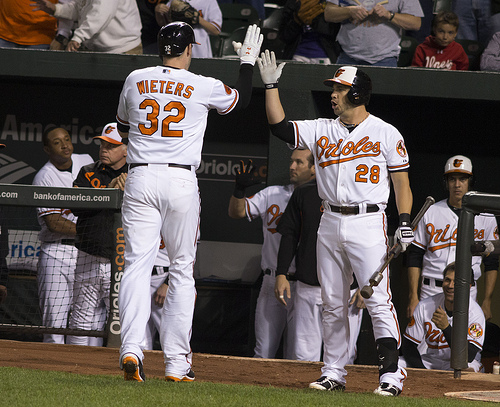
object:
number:
[137, 99, 186, 137]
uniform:
[114, 63, 240, 377]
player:
[405, 154, 499, 321]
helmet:
[444, 155, 475, 191]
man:
[62, 122, 129, 347]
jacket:
[68, 160, 126, 260]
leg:
[347, 215, 409, 398]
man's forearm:
[388, 12, 420, 31]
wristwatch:
[389, 10, 395, 20]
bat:
[361, 196, 436, 298]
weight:
[360, 271, 384, 300]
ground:
[0, 338, 500, 407]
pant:
[316, 201, 408, 393]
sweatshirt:
[414, 36, 469, 71]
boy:
[413, 12, 469, 71]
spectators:
[0, 0, 63, 51]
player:
[255, 46, 415, 399]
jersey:
[286, 114, 410, 205]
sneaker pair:
[308, 375, 403, 397]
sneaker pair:
[120, 352, 196, 383]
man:
[228, 147, 317, 361]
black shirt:
[275, 185, 359, 290]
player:
[113, 21, 265, 383]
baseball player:
[116, 22, 265, 383]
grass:
[0, 360, 500, 407]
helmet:
[158, 20, 202, 55]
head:
[157, 20, 193, 71]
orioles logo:
[315, 135, 381, 169]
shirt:
[325, 0, 425, 66]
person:
[325, 0, 424, 67]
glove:
[232, 24, 264, 67]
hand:
[232, 23, 264, 65]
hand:
[256, 49, 286, 90]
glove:
[256, 48, 286, 89]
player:
[401, 261, 486, 374]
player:
[32, 126, 95, 345]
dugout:
[0, 46, 500, 373]